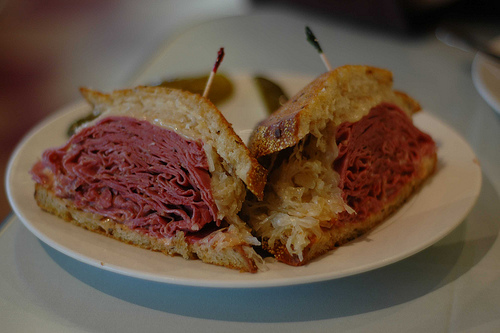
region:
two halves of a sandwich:
[0, 39, 499, 303]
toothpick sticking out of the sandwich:
[196, 40, 230, 105]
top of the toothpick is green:
[297, 22, 322, 54]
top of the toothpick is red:
[208, 42, 231, 74]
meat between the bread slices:
[26, 72, 263, 273]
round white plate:
[8, 52, 498, 292]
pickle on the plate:
[243, 65, 288, 114]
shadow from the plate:
[44, 176, 499, 324]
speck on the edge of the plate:
[96, 257, 108, 271]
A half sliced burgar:
[247, 41, 453, 276]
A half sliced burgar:
[56, 90, 248, 247]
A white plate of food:
[8, 105, 485, 300]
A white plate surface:
[5, 240, 80, 328]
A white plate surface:
[412, 37, 468, 107]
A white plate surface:
[246, 21, 302, 62]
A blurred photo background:
[7, 7, 68, 107]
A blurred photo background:
[91, 5, 207, 60]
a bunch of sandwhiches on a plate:
[15, 49, 480, 316]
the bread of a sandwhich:
[76, 65, 234, 140]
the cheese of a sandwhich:
[106, 101, 176, 141]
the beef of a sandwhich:
[89, 129, 183, 227]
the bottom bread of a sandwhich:
[82, 205, 169, 259]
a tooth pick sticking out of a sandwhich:
[195, 28, 240, 116]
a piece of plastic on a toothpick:
[207, 45, 242, 75]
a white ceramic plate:
[355, 241, 437, 286]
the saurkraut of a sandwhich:
[270, 179, 351, 250]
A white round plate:
[2, 70, 489, 297]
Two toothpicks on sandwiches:
[196, 20, 337, 100]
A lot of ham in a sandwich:
[31, 112, 224, 236]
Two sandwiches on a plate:
[3, 24, 486, 292]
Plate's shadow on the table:
[27, 171, 499, 327]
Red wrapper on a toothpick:
[198, 44, 230, 99]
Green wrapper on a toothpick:
[297, 19, 337, 76]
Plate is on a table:
[3, 9, 499, 330]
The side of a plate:
[468, 29, 499, 121]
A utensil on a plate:
[427, 16, 499, 76]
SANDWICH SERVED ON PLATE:
[3, 44, 490, 295]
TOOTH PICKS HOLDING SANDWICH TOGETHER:
[175, 21, 348, 111]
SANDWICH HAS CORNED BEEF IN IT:
[32, 115, 218, 238]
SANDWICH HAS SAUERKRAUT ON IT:
[266, 159, 355, 265]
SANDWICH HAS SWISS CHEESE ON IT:
[66, 105, 220, 146]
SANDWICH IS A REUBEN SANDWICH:
[29, 72, 429, 272]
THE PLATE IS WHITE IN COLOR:
[2, 66, 485, 294]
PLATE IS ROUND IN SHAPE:
[11, 67, 486, 296]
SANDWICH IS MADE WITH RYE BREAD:
[245, 62, 426, 152]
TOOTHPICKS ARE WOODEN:
[183, 21, 356, 106]